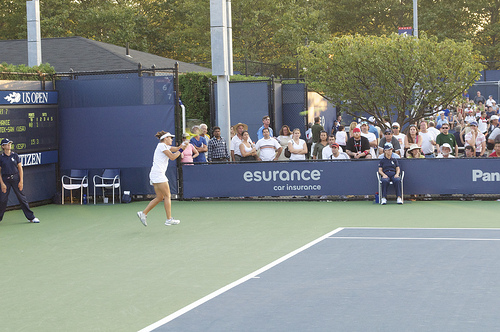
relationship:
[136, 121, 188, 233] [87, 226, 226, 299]
woman jumping off ground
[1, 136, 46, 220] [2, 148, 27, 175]
man wearing shirt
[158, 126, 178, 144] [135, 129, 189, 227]
visor of woman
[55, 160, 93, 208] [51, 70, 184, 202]
chair against wall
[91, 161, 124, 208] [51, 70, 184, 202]
chair against wall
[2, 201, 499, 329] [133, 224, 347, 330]
court with line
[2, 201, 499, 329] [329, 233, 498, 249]
court with line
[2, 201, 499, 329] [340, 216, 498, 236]
court with line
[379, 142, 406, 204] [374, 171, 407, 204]
attendant sitting chair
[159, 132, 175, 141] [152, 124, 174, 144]
visor on player's head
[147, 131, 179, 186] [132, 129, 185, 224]
uniform on player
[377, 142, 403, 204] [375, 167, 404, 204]
woman on chair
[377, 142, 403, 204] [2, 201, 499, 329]
woman on court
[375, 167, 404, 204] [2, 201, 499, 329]
chair on court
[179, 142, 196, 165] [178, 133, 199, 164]
pink shirt on woman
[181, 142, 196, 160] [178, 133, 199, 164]
pink shirt on woman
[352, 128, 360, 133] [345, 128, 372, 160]
red hat on man